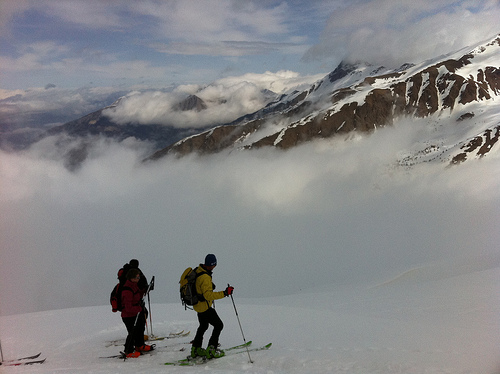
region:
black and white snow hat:
[202, 245, 222, 273]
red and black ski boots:
[123, 336, 155, 371]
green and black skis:
[172, 326, 277, 371]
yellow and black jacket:
[180, 264, 220, 334]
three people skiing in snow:
[82, 235, 257, 370]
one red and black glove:
[208, 281, 239, 315]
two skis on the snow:
[7, 333, 59, 371]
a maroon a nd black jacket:
[102, 285, 144, 335]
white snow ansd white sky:
[255, 193, 440, 373]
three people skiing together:
[91, 233, 266, 368]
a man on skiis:
[185, 241, 241, 371]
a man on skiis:
[100, 256, 157, 366]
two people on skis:
[118, 222, 160, 362]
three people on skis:
[61, 213, 276, 355]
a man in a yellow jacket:
[165, 253, 246, 353]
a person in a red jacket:
[113, 261, 143, 338]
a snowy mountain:
[161, 27, 473, 222]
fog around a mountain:
[1, 111, 417, 253]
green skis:
[183, 317, 290, 372]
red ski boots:
[112, 330, 149, 367]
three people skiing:
[92, 242, 284, 354]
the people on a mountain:
[115, 245, 265, 358]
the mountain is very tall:
[167, 35, 497, 185]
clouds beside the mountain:
[12, 150, 393, 242]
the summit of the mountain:
[140, 90, 287, 116]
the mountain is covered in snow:
[132, 88, 477, 196]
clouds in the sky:
[11, 3, 300, 73]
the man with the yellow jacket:
[180, 255, 241, 321]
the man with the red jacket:
[96, 256, 158, 323]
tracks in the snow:
[47, 337, 375, 372]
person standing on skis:
[162, 241, 278, 368]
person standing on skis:
[95, 263, 201, 370]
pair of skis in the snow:
[161, 330, 278, 372]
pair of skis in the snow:
[101, 333, 208, 367]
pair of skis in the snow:
[89, 320, 198, 354]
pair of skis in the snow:
[0, 346, 55, 369]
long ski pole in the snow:
[221, 278, 265, 369]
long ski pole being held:
[136, 281, 157, 347]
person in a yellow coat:
[162, 246, 270, 371]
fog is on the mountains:
[83, 92, 443, 254]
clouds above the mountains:
[106, 7, 480, 77]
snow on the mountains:
[193, 47, 485, 144]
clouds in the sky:
[49, 13, 448, 66]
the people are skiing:
[102, 255, 285, 360]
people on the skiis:
[108, 322, 281, 369]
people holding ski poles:
[114, 264, 282, 359]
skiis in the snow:
[153, 330, 270, 370]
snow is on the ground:
[286, 288, 473, 368]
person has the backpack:
[177, 249, 243, 319]